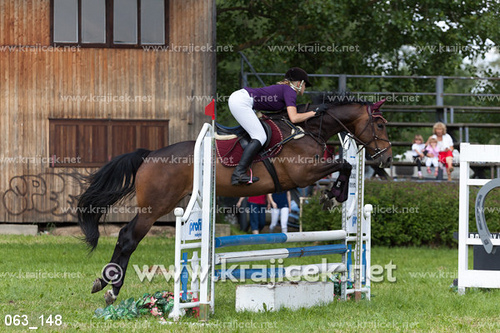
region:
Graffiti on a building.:
[2, 169, 92, 217]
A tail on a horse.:
[66, 147, 156, 249]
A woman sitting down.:
[429, 117, 456, 178]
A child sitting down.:
[411, 132, 429, 169]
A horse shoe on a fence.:
[472, 170, 499, 257]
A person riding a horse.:
[73, 63, 397, 301]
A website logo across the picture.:
[96, 257, 396, 287]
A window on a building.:
[51, 0, 171, 48]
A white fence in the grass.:
[459, 139, 499, 297]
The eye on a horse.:
[375, 120, 387, 131]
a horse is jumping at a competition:
[74, 66, 402, 320]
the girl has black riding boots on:
[228, 137, 266, 183]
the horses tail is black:
[66, 143, 153, 255]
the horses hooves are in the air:
[86, 272, 122, 311]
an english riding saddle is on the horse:
[208, 115, 269, 186]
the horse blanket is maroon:
[210, 121, 285, 168]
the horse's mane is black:
[306, 95, 373, 115]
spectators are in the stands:
[246, 70, 499, 194]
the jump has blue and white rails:
[163, 119, 374, 318]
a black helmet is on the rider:
[281, 68, 309, 93]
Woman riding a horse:
[223, 65, 330, 185]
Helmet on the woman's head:
[282, 65, 316, 87]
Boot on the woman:
[230, 138, 261, 186]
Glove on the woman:
[312, 100, 329, 117]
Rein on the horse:
[320, 103, 392, 161]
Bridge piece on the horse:
[216, 120, 243, 135]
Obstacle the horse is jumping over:
[172, 124, 375, 319]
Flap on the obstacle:
[202, 96, 216, 128]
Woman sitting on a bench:
[423, 120, 453, 181]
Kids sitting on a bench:
[410, 134, 441, 177]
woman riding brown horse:
[223, 67, 323, 182]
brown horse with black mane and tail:
[72, 96, 394, 293]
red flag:
[202, 98, 215, 121]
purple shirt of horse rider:
[242, 75, 293, 109]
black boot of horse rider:
[227, 138, 274, 186]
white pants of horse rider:
[228, 93, 273, 138]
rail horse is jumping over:
[176, 122, 388, 321]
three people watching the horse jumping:
[410, 118, 454, 168]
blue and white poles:
[218, 221, 337, 276]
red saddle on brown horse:
[213, 116, 275, 163]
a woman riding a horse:
[78, 62, 401, 304]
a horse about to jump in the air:
[65, 96, 396, 307]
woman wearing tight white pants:
[228, 85, 267, 140]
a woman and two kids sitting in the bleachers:
[411, 122, 456, 179]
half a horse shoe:
[477, 180, 499, 252]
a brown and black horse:
[75, 99, 392, 306]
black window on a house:
[49, 0, 168, 50]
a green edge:
[299, 174, 498, 247]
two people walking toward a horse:
[238, 190, 291, 233]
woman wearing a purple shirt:
[248, 81, 301, 106]